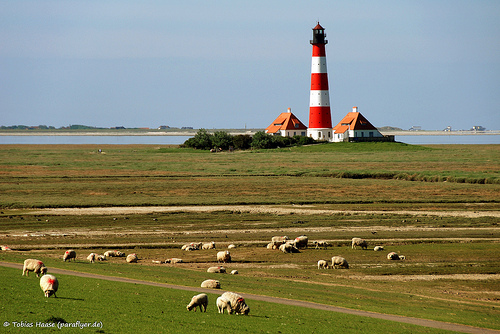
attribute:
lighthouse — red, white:
[293, 10, 339, 137]